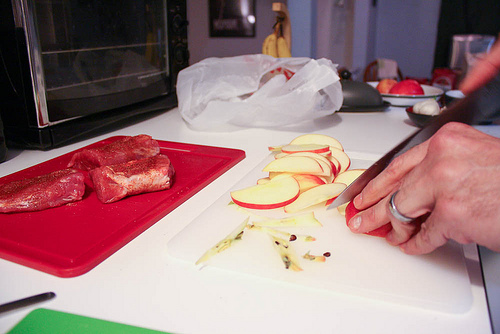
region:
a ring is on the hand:
[388, 188, 410, 225]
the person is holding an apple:
[350, 120, 499, 250]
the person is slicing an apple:
[329, 75, 496, 248]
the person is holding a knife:
[325, 57, 499, 217]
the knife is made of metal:
[326, 68, 493, 217]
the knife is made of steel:
[325, 75, 492, 218]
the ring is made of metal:
[387, 190, 419, 225]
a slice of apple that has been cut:
[231, 170, 302, 210]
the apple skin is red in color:
[230, 188, 307, 210]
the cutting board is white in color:
[173, 139, 478, 307]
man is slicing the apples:
[310, 62, 498, 292]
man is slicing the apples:
[266, 119, 431, 265]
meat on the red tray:
[40, 125, 194, 256]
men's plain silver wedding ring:
[386, 189, 414, 224]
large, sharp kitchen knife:
[324, 71, 499, 215]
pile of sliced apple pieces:
[228, 132, 370, 214]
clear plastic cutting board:
[165, 146, 474, 316]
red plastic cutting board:
[0, 133, 249, 277]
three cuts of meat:
[1, 130, 174, 212]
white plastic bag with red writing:
[173, 53, 344, 131]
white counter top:
[0, 104, 492, 331]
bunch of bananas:
[260, 13, 292, 59]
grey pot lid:
[328, 68, 390, 113]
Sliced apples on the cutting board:
[225, 127, 347, 211]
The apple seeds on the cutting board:
[200, 213, 337, 281]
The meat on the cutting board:
[2, 118, 179, 233]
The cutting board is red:
[36, 218, 117, 255]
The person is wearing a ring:
[383, 188, 415, 226]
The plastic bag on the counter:
[170, 47, 347, 134]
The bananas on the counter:
[255, 2, 305, 58]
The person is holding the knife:
[314, 55, 498, 220]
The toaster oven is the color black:
[3, 0, 237, 152]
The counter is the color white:
[169, 109, 261, 151]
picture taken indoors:
[39, 21, 496, 312]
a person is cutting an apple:
[323, 162, 391, 234]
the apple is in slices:
[227, 123, 319, 213]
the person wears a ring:
[381, 194, 411, 224]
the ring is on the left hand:
[376, 183, 410, 219]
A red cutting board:
[46, 203, 94, 264]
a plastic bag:
[188, 56, 329, 113]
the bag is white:
[223, 94, 290, 127]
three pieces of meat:
[20, 150, 147, 203]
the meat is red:
[13, 126, 156, 211]